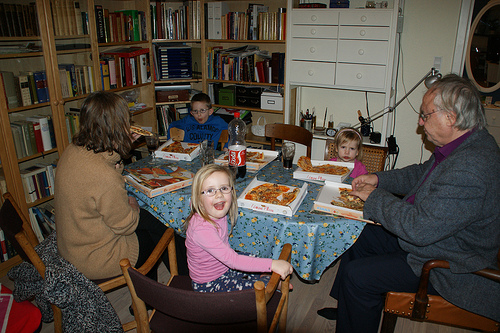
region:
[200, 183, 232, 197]
the little girl is wearing glasses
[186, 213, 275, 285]
the little girl is wearing a long sleeve shirt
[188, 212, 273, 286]
the shirt is pink in color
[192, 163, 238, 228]
the little girl's hair is blonde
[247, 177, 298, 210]
the pizza is in a box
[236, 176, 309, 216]
the box is white in color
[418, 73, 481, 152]
the man's hair is grey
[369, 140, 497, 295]
the man is wearing a coat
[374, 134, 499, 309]
the coat is grey in color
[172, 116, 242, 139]
the boy is wearing a blue shirt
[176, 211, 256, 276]
a girl wearing a pink shirt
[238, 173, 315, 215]
pizza in a white box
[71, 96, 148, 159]
a woman with brown hair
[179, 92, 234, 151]
a boy wearing a blue shirt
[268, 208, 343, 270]
a blue floral table cloth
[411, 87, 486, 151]
a old man wearing glasses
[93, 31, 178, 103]
a shelf filled with books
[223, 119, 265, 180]
a bottle of soda on the table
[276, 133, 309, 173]
a glass sitting on the table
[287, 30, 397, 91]
a white cabinet with drawers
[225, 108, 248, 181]
foreign looking 2 liter Coca-Cola bottle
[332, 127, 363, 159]
child that didn't want her picture taken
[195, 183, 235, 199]
corrective lenses for a little girl's eyes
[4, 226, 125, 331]
as if the brown sweater isn't enough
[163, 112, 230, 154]
right blue long sleeve boy's shirt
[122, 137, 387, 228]
everyone has their own small pizza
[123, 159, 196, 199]
woman wanted to hide her pizza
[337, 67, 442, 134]
silver desk lamp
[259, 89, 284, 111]
white box used to save photos and letters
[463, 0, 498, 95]
oval mirror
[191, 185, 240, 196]
A pair of child sized eyeglasses.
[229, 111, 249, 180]
A bottle of Coca-Cola.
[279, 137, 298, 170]
A glass with dark liquid in it.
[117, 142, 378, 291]
A light blue floral designed tablecloth.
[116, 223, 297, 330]
A wooden chair with brown cushions and backrest.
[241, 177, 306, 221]
A pizza.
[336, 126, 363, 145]
A light colored headband.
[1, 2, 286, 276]
Wooden shelves full of items.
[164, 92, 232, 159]
A young boy in a blue hoodie eating pizza.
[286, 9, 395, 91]
White drawers.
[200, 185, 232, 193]
glasses on the girl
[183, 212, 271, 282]
pink long sleeved shirt on the girl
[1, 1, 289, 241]
bookshelf with many books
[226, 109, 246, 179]
half empty cola bottle on the table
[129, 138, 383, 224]
6 pizzas are on the table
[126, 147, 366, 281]
blue tablecloth with yellow flowers on the table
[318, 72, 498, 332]
man sitting at the table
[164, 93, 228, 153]
young boy in blue jacket sits at the table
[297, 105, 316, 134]
several pencils in a can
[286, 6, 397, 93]
eight white drawers with knobs